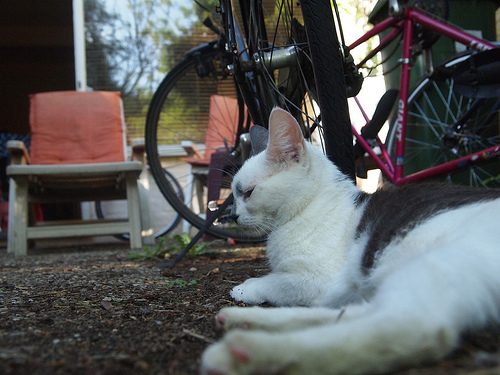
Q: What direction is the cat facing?
A: Left.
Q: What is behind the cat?
A: Bicycle.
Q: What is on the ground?
A: Dirt.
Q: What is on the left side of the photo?
A: Chair.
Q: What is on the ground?
A: Black and white cat.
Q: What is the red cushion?
A: Chair with wood frame.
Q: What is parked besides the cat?
A: A bike.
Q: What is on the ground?
A: Dirt and rocks.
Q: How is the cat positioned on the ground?
A: Lying down.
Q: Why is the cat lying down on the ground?
A: To sleep.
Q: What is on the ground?
A: White and black cat.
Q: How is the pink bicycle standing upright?
A: Kickstand.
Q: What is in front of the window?
A: Two peach chairs.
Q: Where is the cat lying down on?
A: Ground.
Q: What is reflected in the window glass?
A: Trees.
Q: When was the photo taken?
A: Daytime.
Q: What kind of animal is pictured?
A: Cat.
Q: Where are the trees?
A: Reflected in the window.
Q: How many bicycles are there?
A: Two.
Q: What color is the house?
A: Brown.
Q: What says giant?
A: Red bicycle.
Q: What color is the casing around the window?
A: White.